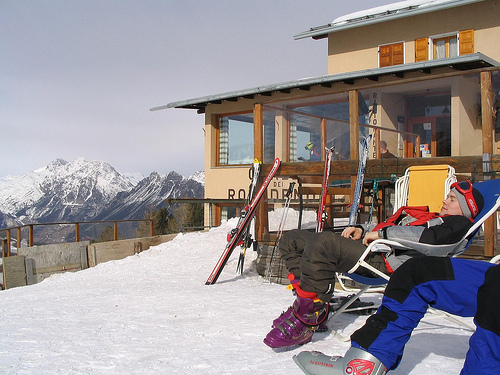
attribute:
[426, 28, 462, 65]
window — square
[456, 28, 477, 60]
shutters — brown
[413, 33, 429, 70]
shutters — brown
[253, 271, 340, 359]
boots — purple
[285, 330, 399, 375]
boots — silver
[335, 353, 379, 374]
design — red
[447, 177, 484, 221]
goggles — red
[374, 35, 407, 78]
window — square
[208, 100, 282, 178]
window — square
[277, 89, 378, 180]
window — square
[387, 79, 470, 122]
window — square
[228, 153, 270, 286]
skis — leaning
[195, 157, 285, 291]
skis — leaning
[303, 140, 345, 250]
skis — leaning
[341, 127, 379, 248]
skis — leaning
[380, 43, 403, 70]
shutters — brown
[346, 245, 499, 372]
ski pants — blue, black, black and blue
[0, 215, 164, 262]
fence — wooden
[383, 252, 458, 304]
patch — black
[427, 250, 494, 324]
pants — blue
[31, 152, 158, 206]
mountains — snow covered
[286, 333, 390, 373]
shoes — grey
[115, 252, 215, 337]
snow — white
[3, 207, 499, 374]
snow — white, packed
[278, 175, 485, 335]
man — reclining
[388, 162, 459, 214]
chairs — stacked, bright, yellow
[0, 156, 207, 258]
mountains — snow capped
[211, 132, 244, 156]
curtains — striped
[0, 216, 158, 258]
fence — wooden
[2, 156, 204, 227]
mountains — snow covered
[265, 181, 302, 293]
poles — ski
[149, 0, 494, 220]
building — multistory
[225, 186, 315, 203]
word — dark